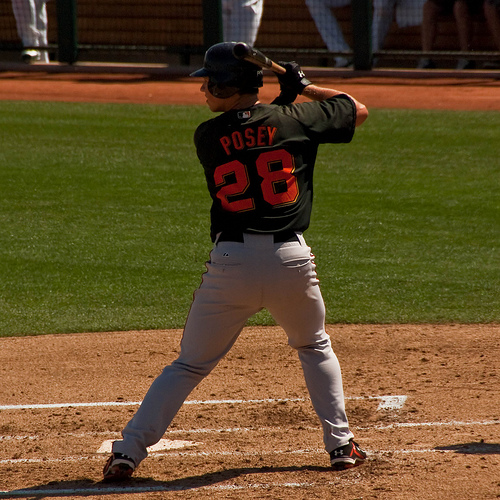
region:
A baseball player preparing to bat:
[98, 41, 378, 482]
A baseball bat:
[233, 40, 287, 77]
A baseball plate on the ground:
[95, 435, 203, 455]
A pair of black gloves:
[270, 56, 310, 96]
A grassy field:
[0, 96, 495, 332]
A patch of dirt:
[0, 321, 497, 496]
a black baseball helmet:
[187, 40, 267, 99]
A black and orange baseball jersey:
[193, 92, 361, 241]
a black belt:
[214, 233, 304, 245]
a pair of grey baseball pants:
[106, 233, 354, 463]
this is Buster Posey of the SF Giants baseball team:
[201, 122, 308, 222]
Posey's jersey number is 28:
[208, 148, 305, 215]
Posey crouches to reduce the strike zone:
[97, 228, 377, 485]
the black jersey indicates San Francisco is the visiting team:
[186, 90, 363, 236]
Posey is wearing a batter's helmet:
[183, 38, 267, 103]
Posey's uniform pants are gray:
[105, 225, 361, 457]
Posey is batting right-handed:
[185, 38, 372, 150]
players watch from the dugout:
[8, 0, 398, 70]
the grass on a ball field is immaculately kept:
[2, 90, 499, 341]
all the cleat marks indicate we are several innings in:
[2, 384, 499, 497]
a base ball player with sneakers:
[335, 449, 367, 464]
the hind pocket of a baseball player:
[286, 253, 314, 271]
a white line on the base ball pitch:
[20, 394, 89, 414]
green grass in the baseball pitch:
[41, 230, 130, 288]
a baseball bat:
[237, 42, 265, 64]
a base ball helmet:
[206, 50, 229, 75]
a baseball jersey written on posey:
[219, 128, 279, 151]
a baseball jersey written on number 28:
[212, 158, 299, 220]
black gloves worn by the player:
[290, 61, 305, 83]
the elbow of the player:
[350, 98, 371, 122]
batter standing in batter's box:
[89, 36, 391, 498]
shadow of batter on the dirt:
[5, 447, 325, 499]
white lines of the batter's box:
[3, 389, 480, 499]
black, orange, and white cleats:
[97, 436, 367, 485]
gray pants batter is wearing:
[105, 235, 352, 457]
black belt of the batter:
[215, 230, 299, 240]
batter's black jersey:
[185, 98, 354, 226]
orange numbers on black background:
[206, 155, 300, 211]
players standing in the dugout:
[5, 5, 499, 70]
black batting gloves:
[275, 61, 311, 103]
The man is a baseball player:
[143, 37, 398, 489]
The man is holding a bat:
[157, 43, 379, 237]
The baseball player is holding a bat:
[172, 26, 359, 246]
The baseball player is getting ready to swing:
[197, 34, 344, 226]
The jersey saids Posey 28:
[188, 114, 316, 231]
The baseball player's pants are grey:
[112, 218, 354, 469]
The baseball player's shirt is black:
[177, 87, 339, 248]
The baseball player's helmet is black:
[169, 26, 278, 111]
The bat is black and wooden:
[222, 27, 313, 97]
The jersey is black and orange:
[180, 85, 341, 245]